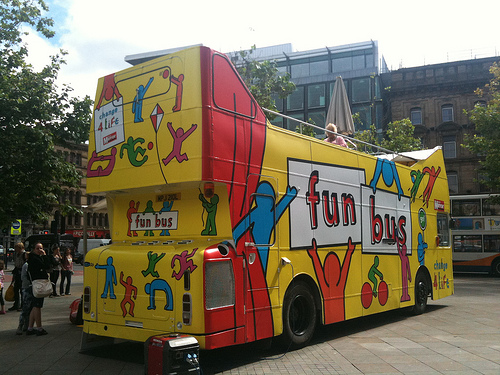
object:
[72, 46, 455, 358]
bus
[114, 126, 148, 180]
paint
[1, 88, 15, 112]
leave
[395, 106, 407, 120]
wall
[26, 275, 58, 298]
bag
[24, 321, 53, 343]
shoe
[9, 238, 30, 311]
man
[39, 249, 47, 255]
hand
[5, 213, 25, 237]
sign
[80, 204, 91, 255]
light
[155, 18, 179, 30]
sky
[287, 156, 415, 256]
logo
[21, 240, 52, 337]
woman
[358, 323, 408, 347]
road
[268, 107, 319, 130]
railing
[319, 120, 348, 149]
person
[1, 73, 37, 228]
tree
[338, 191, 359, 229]
letter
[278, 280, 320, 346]
wheel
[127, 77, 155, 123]
human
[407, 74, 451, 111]
building